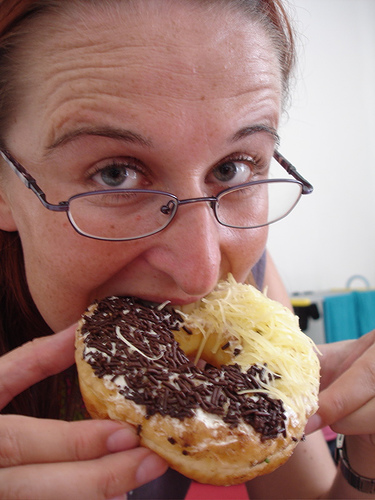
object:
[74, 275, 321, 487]
donut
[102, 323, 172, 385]
sprinkles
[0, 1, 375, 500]
girl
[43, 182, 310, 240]
glasses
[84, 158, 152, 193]
eye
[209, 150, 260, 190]
eye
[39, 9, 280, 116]
forehead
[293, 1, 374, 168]
wall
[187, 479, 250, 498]
shirt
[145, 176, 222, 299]
nose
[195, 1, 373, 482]
right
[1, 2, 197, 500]
left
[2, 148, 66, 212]
wire frame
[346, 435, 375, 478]
wrist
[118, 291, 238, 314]
eaten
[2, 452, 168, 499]
fingers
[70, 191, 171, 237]
lens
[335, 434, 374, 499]
band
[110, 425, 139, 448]
fingernail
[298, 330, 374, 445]
hand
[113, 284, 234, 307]
mouth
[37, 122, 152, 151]
eyebrow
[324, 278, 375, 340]
bag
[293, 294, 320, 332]
bag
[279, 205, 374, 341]
background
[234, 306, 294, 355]
frosting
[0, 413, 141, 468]
finger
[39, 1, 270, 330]
face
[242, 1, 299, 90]
hair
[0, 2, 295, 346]
head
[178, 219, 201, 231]
freckles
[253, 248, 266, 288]
cloth